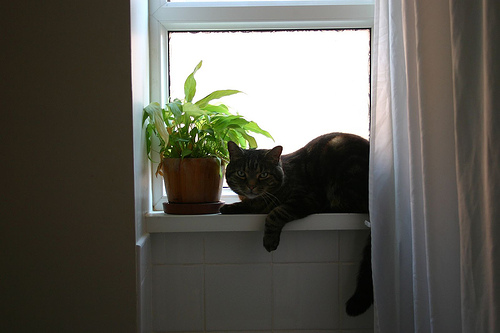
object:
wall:
[1, 2, 140, 332]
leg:
[263, 200, 309, 243]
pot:
[158, 145, 224, 219]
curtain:
[372, 0, 500, 332]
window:
[161, 24, 372, 199]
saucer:
[161, 200, 228, 215]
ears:
[223, 137, 247, 160]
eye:
[256, 170, 274, 182]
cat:
[216, 131, 401, 320]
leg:
[235, 199, 273, 213]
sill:
[145, 199, 370, 233]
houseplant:
[139, 59, 281, 212]